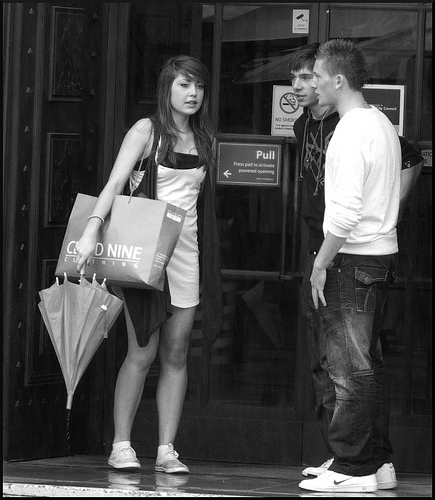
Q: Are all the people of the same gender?
A: No, they are both male and female.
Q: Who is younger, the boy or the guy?
A: The boy is younger than the guy.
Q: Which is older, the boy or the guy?
A: The guy is older than the boy.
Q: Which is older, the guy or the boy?
A: The guy is older than the boy.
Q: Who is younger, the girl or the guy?
A: The girl is younger than the guy.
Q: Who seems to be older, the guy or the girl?
A: The guy is older than the girl.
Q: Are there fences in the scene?
A: No, there are no fences.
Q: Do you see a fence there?
A: No, there are no fences.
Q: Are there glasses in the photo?
A: No, there are no glasses.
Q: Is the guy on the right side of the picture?
A: Yes, the guy is on the right of the image.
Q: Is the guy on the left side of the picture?
A: No, the guy is on the right of the image.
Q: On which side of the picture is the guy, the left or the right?
A: The guy is on the right of the image.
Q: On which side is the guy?
A: The guy is on the right of the image.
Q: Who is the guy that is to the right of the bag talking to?
A: The guy is talking to a girl.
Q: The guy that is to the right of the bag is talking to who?
A: The guy is talking to a girl.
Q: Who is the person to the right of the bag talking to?
A: The guy is talking to a girl.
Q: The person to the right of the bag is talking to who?
A: The guy is talking to a girl.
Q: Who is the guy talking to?
A: The guy is talking to a girl.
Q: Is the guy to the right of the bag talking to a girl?
A: Yes, the guy is talking to a girl.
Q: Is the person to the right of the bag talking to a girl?
A: Yes, the guy is talking to a girl.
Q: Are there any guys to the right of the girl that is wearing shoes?
A: Yes, there is a guy to the right of the girl.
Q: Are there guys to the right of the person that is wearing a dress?
A: Yes, there is a guy to the right of the girl.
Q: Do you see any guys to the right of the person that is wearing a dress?
A: Yes, there is a guy to the right of the girl.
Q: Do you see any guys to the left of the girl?
A: No, the guy is to the right of the girl.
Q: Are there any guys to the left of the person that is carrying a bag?
A: No, the guy is to the right of the girl.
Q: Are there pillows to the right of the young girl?
A: No, there is a guy to the right of the girl.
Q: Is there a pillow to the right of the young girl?
A: No, there is a guy to the right of the girl.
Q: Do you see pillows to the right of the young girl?
A: No, there is a guy to the right of the girl.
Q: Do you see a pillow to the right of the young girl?
A: No, there is a guy to the right of the girl.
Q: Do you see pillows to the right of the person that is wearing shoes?
A: No, there is a guy to the right of the girl.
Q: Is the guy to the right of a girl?
A: Yes, the guy is to the right of a girl.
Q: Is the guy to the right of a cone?
A: No, the guy is to the right of a girl.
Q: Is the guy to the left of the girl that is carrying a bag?
A: No, the guy is to the right of the girl.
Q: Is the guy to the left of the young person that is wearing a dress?
A: No, the guy is to the right of the girl.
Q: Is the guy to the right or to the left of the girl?
A: The guy is to the right of the girl.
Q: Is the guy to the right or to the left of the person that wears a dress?
A: The guy is to the right of the girl.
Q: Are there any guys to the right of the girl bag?
A: Yes, there is a guy to the right of the bag.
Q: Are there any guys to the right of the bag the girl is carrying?
A: Yes, there is a guy to the right of the bag.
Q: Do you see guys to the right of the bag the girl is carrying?
A: Yes, there is a guy to the right of the bag.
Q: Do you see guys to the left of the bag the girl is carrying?
A: No, the guy is to the right of the bag.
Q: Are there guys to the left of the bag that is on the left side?
A: No, the guy is to the right of the bag.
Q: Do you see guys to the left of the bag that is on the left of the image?
A: No, the guy is to the right of the bag.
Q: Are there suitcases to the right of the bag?
A: No, there is a guy to the right of the bag.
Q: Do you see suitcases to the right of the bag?
A: No, there is a guy to the right of the bag.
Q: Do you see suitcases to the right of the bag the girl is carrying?
A: No, there is a guy to the right of the bag.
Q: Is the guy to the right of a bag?
A: Yes, the guy is to the right of a bag.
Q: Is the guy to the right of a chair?
A: No, the guy is to the right of a bag.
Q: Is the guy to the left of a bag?
A: No, the guy is to the right of a bag.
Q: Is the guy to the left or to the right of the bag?
A: The guy is to the right of the bag.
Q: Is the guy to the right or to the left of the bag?
A: The guy is to the right of the bag.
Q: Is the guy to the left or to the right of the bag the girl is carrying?
A: The guy is to the right of the bag.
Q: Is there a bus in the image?
A: No, there are no buses.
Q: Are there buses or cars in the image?
A: No, there are no buses or cars.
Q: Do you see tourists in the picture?
A: No, there are no tourists.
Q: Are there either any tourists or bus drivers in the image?
A: No, there are no tourists or bus drivers.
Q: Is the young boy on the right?
A: Yes, the boy is on the right of the image.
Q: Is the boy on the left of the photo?
A: No, the boy is on the right of the image.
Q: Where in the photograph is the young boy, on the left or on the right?
A: The boy is on the right of the image.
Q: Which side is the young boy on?
A: The boy is on the right of the image.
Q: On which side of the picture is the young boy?
A: The boy is on the right of the image.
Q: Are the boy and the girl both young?
A: Yes, both the boy and the girl are young.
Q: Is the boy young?
A: Yes, the boy is young.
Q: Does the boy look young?
A: Yes, the boy is young.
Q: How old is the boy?
A: The boy is young.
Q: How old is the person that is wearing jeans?
A: The boy is young.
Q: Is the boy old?
A: No, the boy is young.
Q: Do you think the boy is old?
A: No, the boy is young.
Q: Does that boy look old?
A: No, the boy is young.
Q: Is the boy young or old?
A: The boy is young.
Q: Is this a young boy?
A: Yes, this is a young boy.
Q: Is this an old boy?
A: No, this is a young boy.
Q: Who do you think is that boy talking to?
A: The boy is talking to a girl.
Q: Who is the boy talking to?
A: The boy is talking to a girl.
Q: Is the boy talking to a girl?
A: Yes, the boy is talking to a girl.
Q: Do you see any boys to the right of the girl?
A: Yes, there is a boy to the right of the girl.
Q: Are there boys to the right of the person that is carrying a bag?
A: Yes, there is a boy to the right of the girl.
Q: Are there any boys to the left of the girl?
A: No, the boy is to the right of the girl.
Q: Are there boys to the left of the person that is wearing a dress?
A: No, the boy is to the right of the girl.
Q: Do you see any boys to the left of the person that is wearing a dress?
A: No, the boy is to the right of the girl.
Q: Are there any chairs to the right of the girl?
A: No, there is a boy to the right of the girl.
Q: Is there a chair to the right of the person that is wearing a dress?
A: No, there is a boy to the right of the girl.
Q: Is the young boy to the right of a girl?
A: Yes, the boy is to the right of a girl.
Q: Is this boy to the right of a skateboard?
A: No, the boy is to the right of a girl.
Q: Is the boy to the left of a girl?
A: No, the boy is to the right of a girl.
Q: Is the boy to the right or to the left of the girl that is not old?
A: The boy is to the right of the girl.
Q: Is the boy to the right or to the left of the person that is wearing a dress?
A: The boy is to the right of the girl.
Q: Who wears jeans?
A: The boy wears jeans.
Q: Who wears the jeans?
A: The boy wears jeans.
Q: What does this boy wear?
A: The boy wears jeans.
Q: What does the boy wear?
A: The boy wears jeans.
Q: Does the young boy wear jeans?
A: Yes, the boy wears jeans.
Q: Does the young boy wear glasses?
A: No, the boy wears jeans.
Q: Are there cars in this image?
A: No, there are no cars.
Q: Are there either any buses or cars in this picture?
A: No, there are no cars or buses.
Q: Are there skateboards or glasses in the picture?
A: No, there are no glasses or skateboards.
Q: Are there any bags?
A: Yes, there is a bag.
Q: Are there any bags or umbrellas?
A: Yes, there is a bag.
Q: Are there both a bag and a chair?
A: No, there is a bag but no chairs.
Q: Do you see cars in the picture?
A: No, there are no cars.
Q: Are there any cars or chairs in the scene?
A: No, there are no cars or chairs.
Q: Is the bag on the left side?
A: Yes, the bag is on the left of the image.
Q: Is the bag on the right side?
A: No, the bag is on the left of the image.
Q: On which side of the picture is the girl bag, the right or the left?
A: The bag is on the left of the image.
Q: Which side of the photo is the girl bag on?
A: The bag is on the left of the image.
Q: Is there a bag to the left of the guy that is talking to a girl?
A: Yes, there is a bag to the left of the guy.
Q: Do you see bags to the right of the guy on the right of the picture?
A: No, the bag is to the left of the guy.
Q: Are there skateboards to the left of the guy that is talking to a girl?
A: No, there is a bag to the left of the guy.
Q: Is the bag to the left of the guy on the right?
A: Yes, the bag is to the left of the guy.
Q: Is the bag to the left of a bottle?
A: No, the bag is to the left of the guy.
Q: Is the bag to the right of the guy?
A: No, the bag is to the left of the guy.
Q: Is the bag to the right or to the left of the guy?
A: The bag is to the left of the guy.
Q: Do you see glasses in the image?
A: No, there are no glasses.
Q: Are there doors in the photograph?
A: Yes, there is a door.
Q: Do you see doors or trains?
A: Yes, there is a door.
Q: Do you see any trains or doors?
A: Yes, there is a door.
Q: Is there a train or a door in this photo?
A: Yes, there is a door.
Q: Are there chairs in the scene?
A: No, there are no chairs.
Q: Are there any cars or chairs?
A: No, there are no chairs or cars.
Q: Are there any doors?
A: Yes, there is a door.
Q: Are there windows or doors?
A: Yes, there is a door.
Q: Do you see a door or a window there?
A: Yes, there is a door.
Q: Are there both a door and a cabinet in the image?
A: No, there is a door but no cabinets.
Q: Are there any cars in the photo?
A: No, there are no cars.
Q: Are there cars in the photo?
A: No, there are no cars.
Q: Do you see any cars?
A: No, there are no cars.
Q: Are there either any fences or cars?
A: No, there are no cars or fences.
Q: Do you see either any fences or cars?
A: No, there are no cars or fences.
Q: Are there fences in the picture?
A: No, there are no fences.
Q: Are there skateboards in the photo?
A: No, there are no skateboards.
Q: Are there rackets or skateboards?
A: No, there are no skateboards or rackets.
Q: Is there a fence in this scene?
A: No, there are no fences.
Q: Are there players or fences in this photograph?
A: No, there are no fences or players.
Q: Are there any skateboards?
A: No, there are no skateboards.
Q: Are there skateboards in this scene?
A: No, there are no skateboards.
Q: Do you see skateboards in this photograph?
A: No, there are no skateboards.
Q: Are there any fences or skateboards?
A: No, there are no skateboards or fences.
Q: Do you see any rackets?
A: No, there are no rackets.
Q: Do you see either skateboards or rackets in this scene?
A: No, there are no rackets or skateboards.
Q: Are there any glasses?
A: No, there are no glasses.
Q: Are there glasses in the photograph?
A: No, there are no glasses.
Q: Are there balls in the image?
A: No, there are no balls.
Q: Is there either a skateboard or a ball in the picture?
A: No, there are no balls or skateboards.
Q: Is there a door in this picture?
A: Yes, there is a door.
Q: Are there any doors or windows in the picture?
A: Yes, there is a door.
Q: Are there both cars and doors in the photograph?
A: No, there is a door but no cars.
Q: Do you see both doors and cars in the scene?
A: No, there is a door but no cars.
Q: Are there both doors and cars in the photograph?
A: No, there is a door but no cars.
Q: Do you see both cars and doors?
A: No, there is a door but no cars.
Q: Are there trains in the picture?
A: No, there are no trains.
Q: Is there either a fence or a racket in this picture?
A: No, there are no fences or rackets.